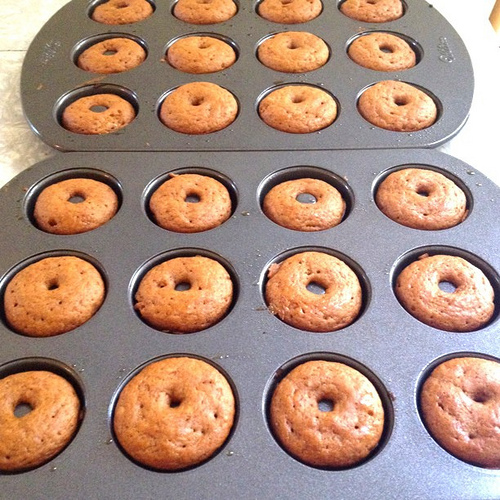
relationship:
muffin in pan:
[167, 75, 251, 137] [41, 0, 472, 165]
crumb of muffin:
[129, 121, 173, 168] [167, 75, 251, 137]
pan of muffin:
[41, 0, 472, 165] [167, 75, 251, 137]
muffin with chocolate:
[167, 75, 251, 137] [158, 382, 184, 421]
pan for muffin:
[41, 0, 472, 165] [167, 75, 251, 137]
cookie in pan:
[265, 225, 361, 338] [41, 0, 472, 165]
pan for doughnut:
[41, 0, 472, 165] [167, 75, 251, 137]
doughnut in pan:
[260, 67, 340, 126] [41, 0, 472, 165]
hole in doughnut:
[385, 83, 421, 116] [260, 67, 340, 126]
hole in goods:
[385, 83, 421, 116] [96, 17, 489, 467]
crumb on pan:
[129, 121, 173, 168] [41, 0, 472, 165]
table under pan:
[439, 8, 497, 184] [41, 0, 472, 165]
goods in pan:
[96, 17, 489, 467] [41, 0, 472, 165]